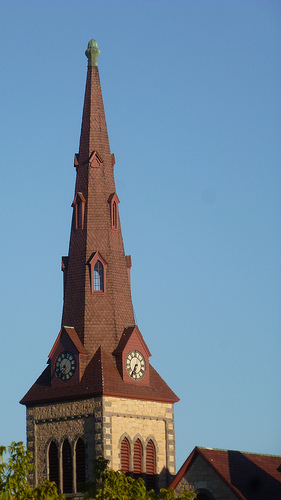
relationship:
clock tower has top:
[16, 34, 185, 497] [80, 30, 106, 72]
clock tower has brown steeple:
[16, 34, 185, 497] [16, 61, 185, 409]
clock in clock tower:
[121, 350, 149, 381] [16, 34, 185, 497]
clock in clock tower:
[51, 352, 78, 382] [16, 34, 185, 497]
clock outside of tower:
[121, 350, 149, 381] [16, 34, 185, 497]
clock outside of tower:
[51, 352, 78, 382] [16, 34, 185, 497]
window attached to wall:
[117, 434, 133, 481] [103, 397, 176, 498]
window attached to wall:
[133, 434, 147, 486] [103, 397, 176, 498]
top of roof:
[80, 30, 106, 72] [16, 61, 185, 409]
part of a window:
[192, 489, 211, 499] [190, 491, 213, 499]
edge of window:
[128, 256, 134, 286] [123, 255, 137, 299]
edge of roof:
[101, 387, 180, 405] [16, 61, 185, 409]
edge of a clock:
[141, 355, 147, 382] [121, 350, 149, 381]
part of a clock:
[130, 362, 137, 378] [121, 350, 149, 381]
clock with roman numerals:
[121, 350, 149, 381] [127, 352, 145, 383]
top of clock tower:
[67, 30, 123, 86] [16, 34, 185, 497]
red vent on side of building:
[74, 434, 88, 491] [16, 34, 185, 497]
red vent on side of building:
[56, 435, 80, 490] [16, 34, 185, 497]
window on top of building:
[190, 491, 213, 499] [153, 438, 277, 498]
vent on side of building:
[117, 434, 133, 481] [16, 34, 185, 497]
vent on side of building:
[133, 434, 147, 486] [16, 34, 185, 497]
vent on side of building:
[145, 435, 158, 490] [16, 34, 185, 497]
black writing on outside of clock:
[127, 352, 145, 383] [121, 350, 149, 381]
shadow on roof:
[227, 449, 279, 498] [162, 444, 276, 493]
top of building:
[80, 30, 106, 72] [16, 34, 185, 497]